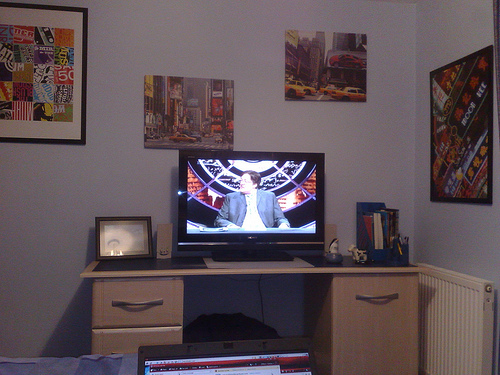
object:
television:
[176, 148, 327, 263]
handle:
[353, 292, 400, 303]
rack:
[354, 200, 413, 268]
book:
[361, 212, 373, 245]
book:
[372, 211, 384, 251]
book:
[380, 207, 391, 253]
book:
[385, 208, 399, 251]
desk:
[78, 252, 433, 373]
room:
[19, 16, 497, 353]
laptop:
[136, 333, 313, 374]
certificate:
[94, 215, 156, 263]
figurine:
[326, 237, 341, 262]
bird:
[81, 249, 434, 360]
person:
[213, 169, 291, 232]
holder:
[355, 201, 399, 266]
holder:
[398, 243, 410, 266]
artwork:
[427, 43, 494, 206]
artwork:
[283, 28, 368, 104]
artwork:
[141, 73, 235, 151]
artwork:
[0, 2, 90, 146]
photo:
[93, 215, 153, 262]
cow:
[347, 242, 369, 264]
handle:
[110, 299, 166, 313]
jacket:
[212, 189, 291, 228]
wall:
[0, 4, 500, 351]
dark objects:
[183, 281, 294, 344]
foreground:
[1, 308, 485, 373]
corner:
[294, 1, 482, 371]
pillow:
[1, 353, 136, 374]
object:
[182, 311, 282, 343]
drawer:
[90, 275, 186, 330]